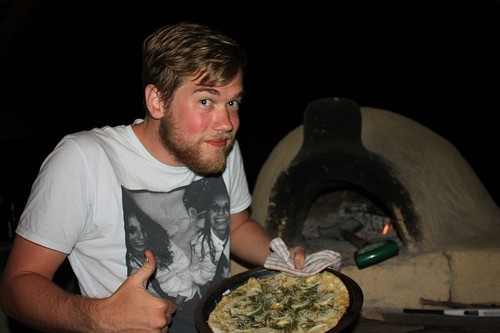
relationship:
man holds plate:
[14, 16, 295, 329] [193, 259, 370, 332]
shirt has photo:
[15, 122, 250, 294] [119, 183, 235, 282]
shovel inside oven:
[317, 216, 398, 270] [260, 89, 473, 258]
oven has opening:
[260, 89, 473, 258] [283, 94, 391, 248]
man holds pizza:
[14, 16, 295, 329] [209, 271, 350, 329]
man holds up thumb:
[14, 16, 295, 329] [130, 246, 165, 285]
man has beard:
[14, 16, 295, 329] [156, 116, 237, 181]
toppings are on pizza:
[252, 292, 273, 313] [209, 271, 350, 329]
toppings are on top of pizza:
[252, 292, 273, 313] [209, 271, 350, 329]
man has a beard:
[14, 16, 295, 329] [156, 116, 237, 181]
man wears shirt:
[14, 16, 295, 329] [15, 122, 250, 294]